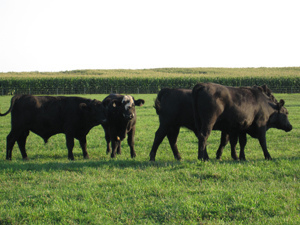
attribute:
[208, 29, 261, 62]
clouds — white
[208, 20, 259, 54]
sky — blue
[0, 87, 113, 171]
cow — black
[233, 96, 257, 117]
fur — black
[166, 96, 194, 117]
fur — black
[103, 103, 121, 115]
fur — black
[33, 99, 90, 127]
fur — black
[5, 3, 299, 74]
sky — blue, bright, white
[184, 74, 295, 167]
cow — black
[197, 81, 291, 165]
cow — black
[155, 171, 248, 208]
grass — green, thick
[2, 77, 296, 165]
cows — four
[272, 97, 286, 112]
ears — dark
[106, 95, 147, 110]
ears — dark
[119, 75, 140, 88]
corn stalks — tall, green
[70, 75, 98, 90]
corn stalks — tall, green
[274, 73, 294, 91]
corn stalks — tall, green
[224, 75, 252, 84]
corn stalks — tall, green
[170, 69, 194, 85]
corn stalks — tall, green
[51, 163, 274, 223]
grass — green 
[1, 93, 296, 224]
grassy — area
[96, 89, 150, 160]
cow — black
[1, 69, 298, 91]
corn — tall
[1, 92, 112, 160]
cow — black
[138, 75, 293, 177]
cow — black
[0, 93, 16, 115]
tail — long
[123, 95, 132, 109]
spot — white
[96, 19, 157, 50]
cloud — white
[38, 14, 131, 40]
cloud — white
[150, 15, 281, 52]
sky — blue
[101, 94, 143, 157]
cow — black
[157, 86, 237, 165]
cow — black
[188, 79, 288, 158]
cow — black